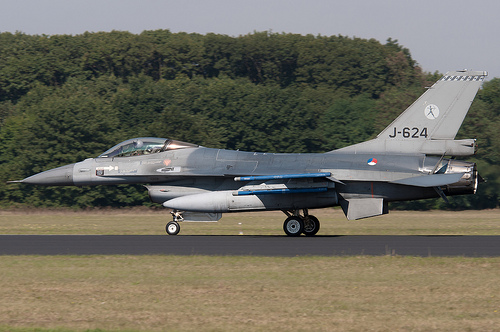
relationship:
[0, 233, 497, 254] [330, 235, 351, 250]
asphalt has patch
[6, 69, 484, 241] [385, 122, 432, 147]
plane says j-624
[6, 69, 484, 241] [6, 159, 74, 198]
plane has front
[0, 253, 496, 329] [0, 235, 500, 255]
area beside asphalt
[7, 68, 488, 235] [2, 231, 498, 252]
airplane on runway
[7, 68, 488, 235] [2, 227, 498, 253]
airplane on runway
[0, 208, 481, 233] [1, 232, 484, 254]
area beside a runway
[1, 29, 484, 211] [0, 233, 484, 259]
trees standing beside a runway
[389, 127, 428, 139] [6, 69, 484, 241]
j-624 on plane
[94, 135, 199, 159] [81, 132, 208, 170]
window over cockpit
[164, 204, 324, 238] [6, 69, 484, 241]
gear on a plane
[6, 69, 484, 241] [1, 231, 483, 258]
plane on a runway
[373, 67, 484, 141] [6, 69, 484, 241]
tail on a plane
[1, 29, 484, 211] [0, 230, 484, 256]
trees on side of runway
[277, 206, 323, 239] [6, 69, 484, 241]
wheels on plane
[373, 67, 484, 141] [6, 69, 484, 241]
tail of plane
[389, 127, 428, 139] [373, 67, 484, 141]
j-624 of tail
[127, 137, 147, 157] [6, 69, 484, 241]
pilot on plane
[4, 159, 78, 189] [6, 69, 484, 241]
nose of plane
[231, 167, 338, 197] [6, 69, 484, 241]
wing on plane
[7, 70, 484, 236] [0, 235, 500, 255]
airplane on asphalt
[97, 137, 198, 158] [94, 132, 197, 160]
window around cockpit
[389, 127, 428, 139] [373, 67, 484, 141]
j-624 on tail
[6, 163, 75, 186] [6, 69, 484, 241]
nose of plane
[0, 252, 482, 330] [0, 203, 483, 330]
grass on ground